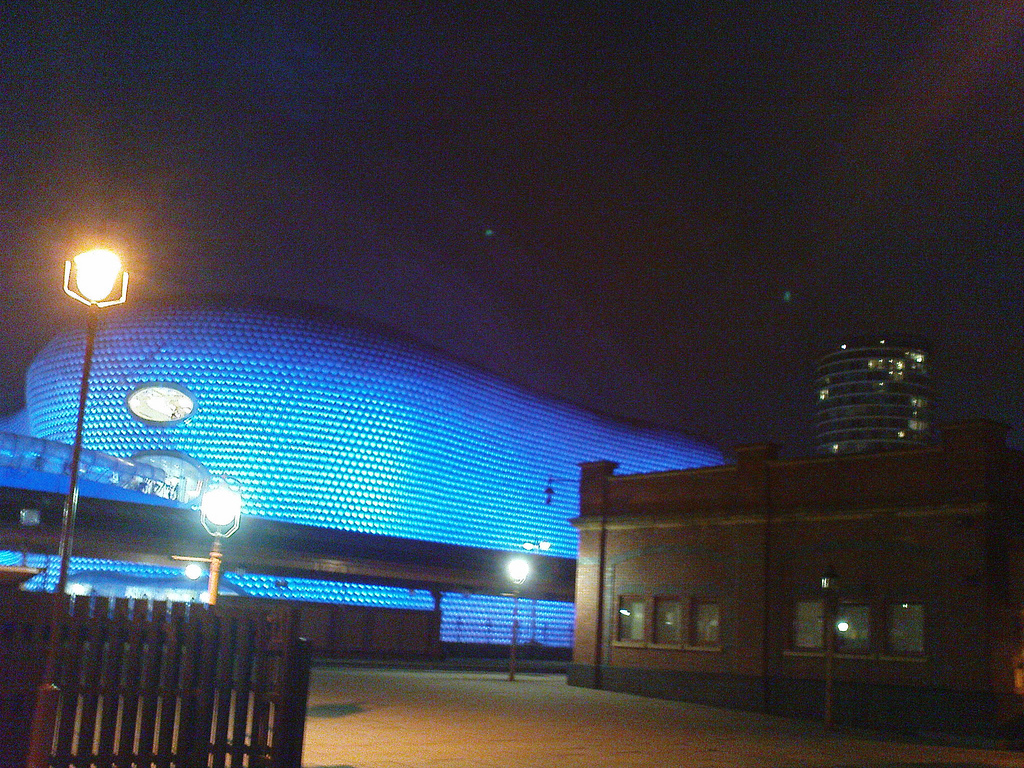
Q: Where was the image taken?
A: It was taken at the city.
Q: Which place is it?
A: It is a city.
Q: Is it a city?
A: Yes, it is a city.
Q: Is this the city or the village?
A: It is the city.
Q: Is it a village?
A: No, it is a city.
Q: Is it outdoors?
A: Yes, it is outdoors.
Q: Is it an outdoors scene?
A: Yes, it is outdoors.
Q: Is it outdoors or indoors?
A: It is outdoors.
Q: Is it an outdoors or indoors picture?
A: It is outdoors.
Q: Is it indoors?
A: No, it is outdoors.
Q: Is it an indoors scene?
A: No, it is outdoors.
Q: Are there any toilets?
A: No, there are no toilets.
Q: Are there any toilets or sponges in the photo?
A: No, there are no toilets or sponges.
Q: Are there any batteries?
A: No, there are no batteries.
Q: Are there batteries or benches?
A: No, there are no batteries or benches.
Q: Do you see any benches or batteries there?
A: No, there are no batteries or benches.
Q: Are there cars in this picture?
A: No, there are no cars.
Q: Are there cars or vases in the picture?
A: No, there are no cars or vases.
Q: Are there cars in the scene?
A: No, there are no cars.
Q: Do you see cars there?
A: No, there are no cars.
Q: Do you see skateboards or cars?
A: No, there are no cars or skateboards.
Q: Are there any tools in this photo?
A: No, there are no tools.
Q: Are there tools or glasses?
A: No, there are no tools or glasses.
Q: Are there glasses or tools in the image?
A: No, there are no tools or glasses.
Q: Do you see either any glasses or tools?
A: No, there are no tools or glasses.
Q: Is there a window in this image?
A: Yes, there is a window.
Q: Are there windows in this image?
A: Yes, there is a window.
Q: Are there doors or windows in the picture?
A: Yes, there is a window.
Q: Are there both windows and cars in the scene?
A: No, there is a window but no cars.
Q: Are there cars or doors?
A: No, there are no cars or doors.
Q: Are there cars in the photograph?
A: No, there are no cars.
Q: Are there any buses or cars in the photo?
A: No, there are no cars or buses.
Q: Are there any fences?
A: Yes, there is a fence.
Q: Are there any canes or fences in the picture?
A: Yes, there is a fence.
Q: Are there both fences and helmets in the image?
A: No, there is a fence but no helmets.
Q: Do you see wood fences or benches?
A: Yes, there is a wood fence.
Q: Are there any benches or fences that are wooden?
A: Yes, the fence is wooden.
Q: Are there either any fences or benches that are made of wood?
A: Yes, the fence is made of wood.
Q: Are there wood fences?
A: Yes, there is a wood fence.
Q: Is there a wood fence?
A: Yes, there is a wood fence.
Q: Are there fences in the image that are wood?
A: Yes, there is a wood fence.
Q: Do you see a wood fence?
A: Yes, there is a wood fence.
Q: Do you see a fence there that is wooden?
A: Yes, there is a fence that is wooden.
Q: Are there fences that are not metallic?
A: Yes, there is a wooden fence.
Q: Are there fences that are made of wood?
A: Yes, there is a fence that is made of wood.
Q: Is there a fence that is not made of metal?
A: Yes, there is a fence that is made of wood.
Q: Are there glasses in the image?
A: No, there are no glasses.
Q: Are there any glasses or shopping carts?
A: No, there are no glasses or shopping carts.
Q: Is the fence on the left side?
A: Yes, the fence is on the left of the image.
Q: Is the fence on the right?
A: No, the fence is on the left of the image.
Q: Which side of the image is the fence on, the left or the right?
A: The fence is on the left of the image.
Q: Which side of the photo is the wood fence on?
A: The fence is on the left of the image.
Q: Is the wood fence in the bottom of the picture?
A: Yes, the fence is in the bottom of the image.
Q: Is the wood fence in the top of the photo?
A: No, the fence is in the bottom of the image.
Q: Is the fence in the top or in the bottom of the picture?
A: The fence is in the bottom of the image.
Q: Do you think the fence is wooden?
A: Yes, the fence is wooden.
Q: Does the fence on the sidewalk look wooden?
A: Yes, the fence is wooden.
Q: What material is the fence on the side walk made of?
A: The fence is made of wood.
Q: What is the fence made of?
A: The fence is made of wood.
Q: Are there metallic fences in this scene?
A: No, there is a fence but it is wooden.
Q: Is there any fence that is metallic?
A: No, there is a fence but it is wooden.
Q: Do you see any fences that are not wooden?
A: No, there is a fence but it is wooden.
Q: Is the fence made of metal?
A: No, the fence is made of wood.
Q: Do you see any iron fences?
A: No, there is a fence but it is made of wood.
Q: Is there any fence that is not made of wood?
A: No, there is a fence but it is made of wood.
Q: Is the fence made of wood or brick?
A: The fence is made of wood.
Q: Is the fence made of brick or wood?
A: The fence is made of wood.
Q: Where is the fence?
A: The fence is on the sidewalk.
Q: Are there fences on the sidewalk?
A: Yes, there is a fence on the sidewalk.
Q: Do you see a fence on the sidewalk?
A: Yes, there is a fence on the sidewalk.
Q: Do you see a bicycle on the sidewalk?
A: No, there is a fence on the sidewalk.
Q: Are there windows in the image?
A: Yes, there is a window.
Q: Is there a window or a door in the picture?
A: Yes, there is a window.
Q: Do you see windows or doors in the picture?
A: Yes, there is a window.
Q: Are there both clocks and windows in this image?
A: No, there is a window but no clocks.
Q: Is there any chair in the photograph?
A: No, there are no chairs.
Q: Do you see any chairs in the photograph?
A: No, there are no chairs.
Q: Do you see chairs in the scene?
A: No, there are no chairs.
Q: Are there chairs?
A: No, there are no chairs.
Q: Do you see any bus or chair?
A: No, there are no chairs or buses.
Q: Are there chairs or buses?
A: No, there are no chairs or buses.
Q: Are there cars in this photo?
A: No, there are no cars.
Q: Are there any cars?
A: No, there are no cars.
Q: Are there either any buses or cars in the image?
A: No, there are no cars or buses.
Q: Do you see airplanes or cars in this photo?
A: No, there are no cars or airplanes.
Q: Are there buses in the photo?
A: No, there are no buses.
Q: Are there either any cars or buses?
A: No, there are no buses or cars.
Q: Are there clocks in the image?
A: No, there are no clocks.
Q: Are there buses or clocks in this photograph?
A: No, there are no clocks or buses.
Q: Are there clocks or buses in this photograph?
A: No, there are no clocks or buses.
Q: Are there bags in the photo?
A: No, there are no bags.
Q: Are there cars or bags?
A: No, there are no bags or cars.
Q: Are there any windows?
A: Yes, there is a window.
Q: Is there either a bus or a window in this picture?
A: Yes, there is a window.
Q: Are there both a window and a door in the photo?
A: No, there is a window but no doors.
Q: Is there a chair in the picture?
A: No, there are no chairs.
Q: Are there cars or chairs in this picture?
A: No, there are no chairs or cars.